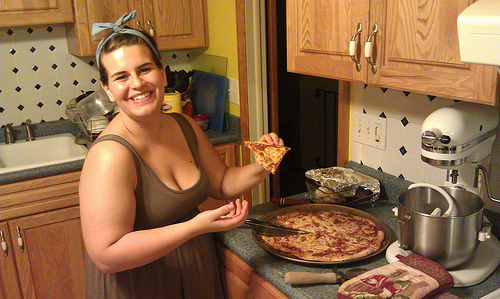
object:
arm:
[77, 140, 194, 274]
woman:
[76, 28, 287, 299]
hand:
[192, 198, 249, 234]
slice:
[245, 137, 292, 176]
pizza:
[259, 208, 386, 263]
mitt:
[338, 251, 455, 299]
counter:
[219, 159, 500, 299]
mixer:
[384, 101, 498, 288]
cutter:
[281, 266, 372, 285]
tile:
[37, 66, 60, 88]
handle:
[362, 24, 380, 75]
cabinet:
[363, 0, 498, 109]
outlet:
[351, 111, 389, 151]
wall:
[349, 82, 498, 211]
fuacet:
[21, 119, 36, 141]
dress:
[79, 111, 229, 298]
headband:
[90, 10, 160, 66]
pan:
[249, 203, 391, 266]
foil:
[305, 164, 382, 207]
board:
[188, 50, 229, 131]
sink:
[0, 132, 89, 176]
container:
[157, 91, 184, 115]